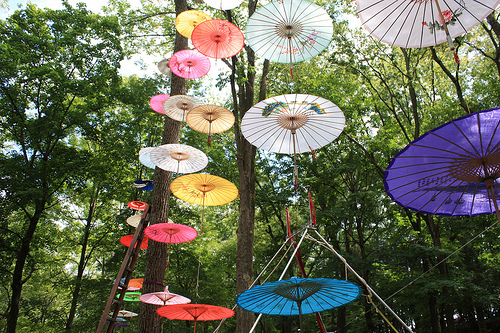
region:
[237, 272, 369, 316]
Blue umbrella in trees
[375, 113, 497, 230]
Part of a purple umbrella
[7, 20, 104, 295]
Dark green trees all around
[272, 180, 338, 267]
Red tails hanging from trees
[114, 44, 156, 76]
Sunlight coming through the trees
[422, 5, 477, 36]
Rose pattern on umbrella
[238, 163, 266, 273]
Tall brown tree trunk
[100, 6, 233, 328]
umbrellas hanging from tree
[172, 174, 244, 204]
Yellow umbrella in the middle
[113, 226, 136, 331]
Ladder up against the tree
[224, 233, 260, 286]
stem of a tree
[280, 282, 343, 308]
part of a blue umbrella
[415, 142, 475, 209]
part of a purple umbrella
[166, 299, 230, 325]
part of a red umbrella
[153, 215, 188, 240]
part of a pink umbrella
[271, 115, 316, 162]
part of a white umbrella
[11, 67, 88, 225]
some tree green branches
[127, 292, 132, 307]
part of a green umbrella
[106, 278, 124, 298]
part of a wooden ladder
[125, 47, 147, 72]
part of the cloudy sky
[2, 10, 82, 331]
this is a tree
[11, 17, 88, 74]
the leaves are green in color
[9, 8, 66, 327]
the tree is tall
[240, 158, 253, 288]
the trunk is brown in color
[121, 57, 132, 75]
this is the sky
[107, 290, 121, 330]
this is a ladder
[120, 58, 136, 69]
the sky has clouds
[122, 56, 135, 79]
the clouds are white in color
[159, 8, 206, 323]
these are some umbrellas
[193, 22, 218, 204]
the umbrellas have several colors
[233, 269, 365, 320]
bright blue parasol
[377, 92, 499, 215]
bright purple parasol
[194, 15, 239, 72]
bright red parasol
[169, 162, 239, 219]
yellow opened parasol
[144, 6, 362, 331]
many parasols in a tree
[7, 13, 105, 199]
green leaves on a tree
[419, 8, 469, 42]
flower design on a parasol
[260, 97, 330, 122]
dragon design on a parasol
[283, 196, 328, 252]
red string from the bottom of a parasol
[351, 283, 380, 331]
yellow string attached to a parasol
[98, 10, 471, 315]
umbrellas against tall trees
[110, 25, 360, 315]
umbrellas in vertical rows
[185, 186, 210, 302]
cord connecting top of umbrella to handle above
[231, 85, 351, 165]
white umbrella with arch of colors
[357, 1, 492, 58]
flower, bud and leaf on white umbrella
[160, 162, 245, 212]
light shining through yellow umbrella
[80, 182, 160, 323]
curved ladder leaning on tree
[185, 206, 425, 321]
metal structure wider at bottom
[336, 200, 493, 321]
string reaching across umbrella display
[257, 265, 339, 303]
woven sticks forming inner frame